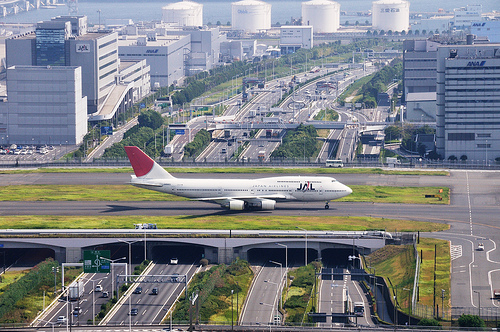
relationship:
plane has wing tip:
[123, 141, 354, 211] [125, 144, 162, 179]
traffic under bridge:
[79, 249, 181, 274] [0, 155, 384, 248]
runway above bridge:
[0, 163, 490, 224] [2, 166, 385, 281]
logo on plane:
[293, 178, 319, 196] [123, 142, 354, 212]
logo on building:
[292, 180, 322, 198] [72, 25, 153, 133]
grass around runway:
[5, 216, 435, 230] [0, 187, 450, 217]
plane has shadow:
[123, 142, 354, 212] [94, 202, 329, 222]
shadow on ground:
[94, 202, 329, 222] [0, 163, 499, 318]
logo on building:
[462, 56, 493, 77] [439, 53, 497, 163]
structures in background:
[137, 0, 423, 47] [94, 0, 453, 83]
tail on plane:
[117, 139, 171, 194] [103, 121, 361, 237]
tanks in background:
[163, 0, 418, 34] [69, 1, 425, 49]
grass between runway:
[18, 177, 445, 208] [3, 203, 426, 217]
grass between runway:
[18, 177, 445, 208] [10, 176, 450, 184]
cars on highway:
[81, 262, 171, 305] [38, 254, 186, 320]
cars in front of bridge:
[81, 262, 171, 305] [10, 234, 393, 261]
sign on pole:
[82, 252, 111, 278] [57, 257, 133, 289]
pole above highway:
[57, 257, 133, 289] [48, 256, 185, 321]